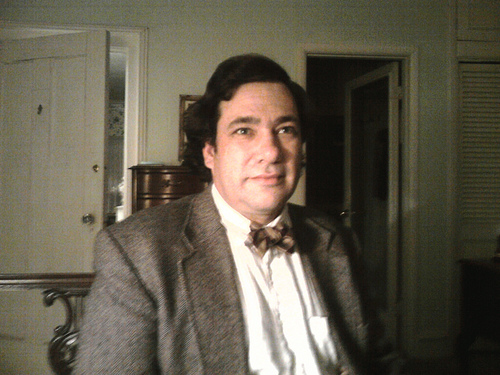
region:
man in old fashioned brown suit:
[64, 50, 419, 373]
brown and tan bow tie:
[243, 224, 302, 266]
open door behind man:
[293, 41, 421, 367]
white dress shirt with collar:
[209, 183, 326, 371]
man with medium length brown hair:
[163, 46, 326, 218]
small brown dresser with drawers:
[120, 156, 196, 207]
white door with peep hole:
[6, 39, 105, 364]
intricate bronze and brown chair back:
[0, 263, 83, 372]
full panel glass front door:
[337, 75, 399, 337]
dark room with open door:
[298, 46, 407, 353]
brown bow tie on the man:
[234, 216, 304, 265]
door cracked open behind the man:
[40, 14, 135, 244]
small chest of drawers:
[124, 155, 204, 207]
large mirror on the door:
[351, 83, 384, 270]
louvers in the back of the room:
[461, 63, 495, 230]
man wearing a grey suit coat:
[111, 208, 374, 362]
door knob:
[77, 203, 98, 228]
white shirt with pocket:
[247, 268, 325, 371]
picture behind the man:
[169, 90, 206, 170]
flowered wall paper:
[107, 102, 124, 137]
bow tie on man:
[232, 214, 299, 249]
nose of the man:
[261, 148, 286, 178]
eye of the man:
[229, 119, 261, 153]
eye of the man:
[277, 114, 299, 139]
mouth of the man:
[249, 168, 290, 193]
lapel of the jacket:
[171, 224, 210, 296]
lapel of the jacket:
[310, 230, 362, 300]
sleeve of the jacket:
[55, 233, 161, 372]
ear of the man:
[190, 140, 220, 176]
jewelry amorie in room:
[128, 154, 175, 203]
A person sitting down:
[62, 46, 412, 373]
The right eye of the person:
[231, 125, 256, 137]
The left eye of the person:
[272, 123, 299, 136]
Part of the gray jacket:
[140, 247, 163, 292]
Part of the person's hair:
[224, 66, 248, 78]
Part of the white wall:
[184, 19, 216, 51]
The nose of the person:
[256, 123, 286, 165]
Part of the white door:
[33, 148, 54, 232]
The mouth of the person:
[242, 170, 296, 187]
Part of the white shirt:
[278, 298, 297, 344]